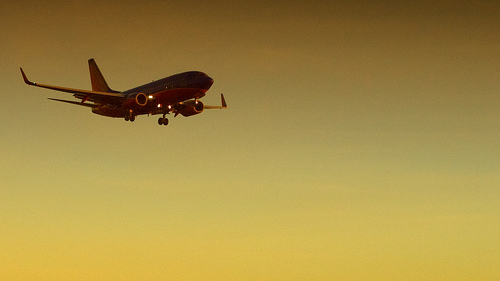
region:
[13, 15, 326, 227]
opening credits of golden girls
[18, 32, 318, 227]
passenger airplane flying in sky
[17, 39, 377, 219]
yellow sunny sky with airplane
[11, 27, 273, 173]
commercial jetliner flying in sky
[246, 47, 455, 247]
yellow blue sky at sunset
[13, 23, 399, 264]
plane flying into the sunset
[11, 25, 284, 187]
plane in sky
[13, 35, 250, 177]
wings and jets of plane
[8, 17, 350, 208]
plane just before landing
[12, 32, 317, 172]
plane flying down to land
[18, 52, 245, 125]
one plane is flying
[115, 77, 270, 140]
the plane has two engines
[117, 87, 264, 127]
the lights are turned on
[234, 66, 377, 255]
the sky is yellow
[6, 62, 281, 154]
the plane has wings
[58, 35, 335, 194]
the plane is a passenger plane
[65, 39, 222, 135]
the plane has tail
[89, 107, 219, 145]
the wheels are black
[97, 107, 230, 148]
the plane has wheels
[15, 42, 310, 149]
the plane is blue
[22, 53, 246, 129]
An airplane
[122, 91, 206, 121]
Two engines.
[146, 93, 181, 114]
Lights on the plane.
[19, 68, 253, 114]
Wings of the plane.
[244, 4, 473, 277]
A dark yellowish sky.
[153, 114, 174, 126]
Wheels under the plane.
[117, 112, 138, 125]
More wheels under the plane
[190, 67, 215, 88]
Windshield in the front of the plane.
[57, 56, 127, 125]
Tail of the plane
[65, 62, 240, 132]
Color blocked airplane.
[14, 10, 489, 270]
Picture is taken outside.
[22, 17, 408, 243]
Picture taken during dawn.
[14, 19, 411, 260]
A plane is in the air.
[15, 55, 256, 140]
The plane's body is red and blue.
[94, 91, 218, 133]
The plane has two engines.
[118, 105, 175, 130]
The plane's wheels are down.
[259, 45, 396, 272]
The sky is yellow and light brown.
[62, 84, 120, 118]
The plane's wing flap is down.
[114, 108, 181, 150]
The plane has two sets of rear tires.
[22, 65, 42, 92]
The light on the plane's wing is on.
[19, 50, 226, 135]
a plane in the sky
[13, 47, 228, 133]
a plane is flying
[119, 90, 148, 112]
a plane's right engine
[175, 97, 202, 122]
a plane's left engine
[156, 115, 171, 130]
a plane's wheels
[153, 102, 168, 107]
a plane's lights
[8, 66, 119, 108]
a plane's right wing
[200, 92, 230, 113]
a plane's left wing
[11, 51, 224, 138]
a plane about to land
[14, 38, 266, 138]
a plane that had just took off